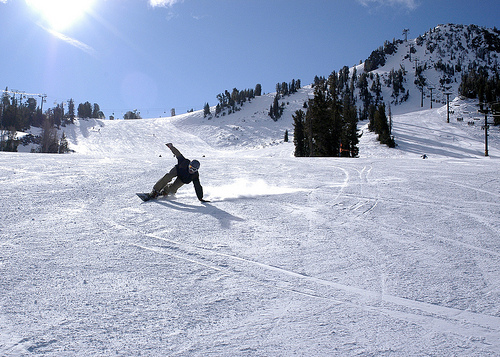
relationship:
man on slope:
[133, 142, 213, 205] [119, 169, 347, 272]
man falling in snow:
[133, 142, 213, 205] [8, 32, 492, 349]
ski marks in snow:
[145, 161, 495, 341] [4, 94, 494, 350]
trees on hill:
[359, 21, 499, 103] [0, 22, 499, 158]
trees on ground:
[292, 84, 361, 154] [6, 112, 498, 348]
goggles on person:
[190, 166, 197, 170] [151, 142, 209, 205]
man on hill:
[148, 142, 210, 207] [14, 22, 498, 347]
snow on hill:
[4, 94, 494, 350] [14, 22, 498, 347]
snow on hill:
[4, 94, 494, 350] [9, 63, 486, 349]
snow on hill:
[1, 63, 497, 351] [9, 63, 486, 349]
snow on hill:
[4, 94, 494, 350] [6, 93, 491, 349]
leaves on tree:
[307, 96, 341, 140] [292, 80, 364, 156]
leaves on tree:
[316, 143, 324, 150] [292, 80, 364, 156]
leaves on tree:
[380, 110, 390, 132] [365, 91, 393, 145]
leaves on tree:
[275, 77, 337, 172] [283, 92, 340, 155]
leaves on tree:
[261, 85, 289, 125] [265, 81, 292, 131]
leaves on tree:
[449, 55, 488, 119] [441, 43, 482, 108]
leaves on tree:
[58, 60, 112, 142] [64, 82, 98, 139]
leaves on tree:
[42, 85, 90, 136] [33, 70, 99, 143]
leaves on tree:
[352, 9, 422, 93] [359, 19, 413, 101]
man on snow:
[133, 142, 213, 205] [39, 129, 439, 352]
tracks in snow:
[137, 208, 474, 354] [59, 100, 485, 353]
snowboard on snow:
[132, 183, 161, 213] [22, 163, 476, 353]